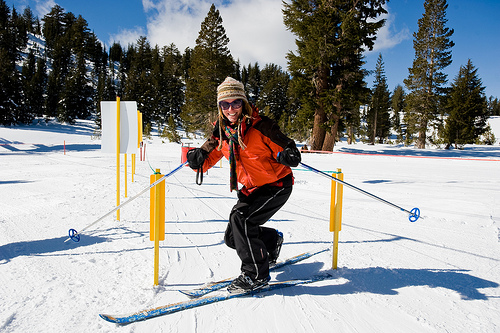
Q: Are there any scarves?
A: Yes, there is a scarf.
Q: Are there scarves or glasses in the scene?
A: Yes, there is a scarf.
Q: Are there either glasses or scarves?
A: Yes, there is a scarf.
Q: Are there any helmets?
A: No, there are no helmets.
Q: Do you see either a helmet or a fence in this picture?
A: No, there are no helmets or fences.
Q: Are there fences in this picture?
A: No, there are no fences.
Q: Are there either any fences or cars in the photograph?
A: No, there are no fences or cars.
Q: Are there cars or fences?
A: No, there are no fences or cars.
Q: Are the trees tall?
A: Yes, the trees are tall.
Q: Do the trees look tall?
A: Yes, the trees are tall.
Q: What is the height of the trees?
A: The trees are tall.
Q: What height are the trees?
A: The trees are tall.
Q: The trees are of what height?
A: The trees are tall.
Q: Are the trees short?
A: No, the trees are tall.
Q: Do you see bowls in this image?
A: No, there are no bowls.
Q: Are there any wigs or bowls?
A: No, there are no bowls or wigs.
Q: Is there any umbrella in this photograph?
A: No, there are no umbrellas.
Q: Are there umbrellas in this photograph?
A: No, there are no umbrellas.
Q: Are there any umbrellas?
A: No, there are no umbrellas.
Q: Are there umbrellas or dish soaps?
A: No, there are no umbrellas or dish soaps.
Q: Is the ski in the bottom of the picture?
A: Yes, the ski is in the bottom of the image.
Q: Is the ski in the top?
A: No, the ski is in the bottom of the image.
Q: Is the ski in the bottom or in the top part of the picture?
A: The ski is in the bottom of the image.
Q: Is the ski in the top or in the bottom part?
A: The ski is in the bottom of the image.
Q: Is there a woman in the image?
A: Yes, there is a woman.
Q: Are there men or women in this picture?
A: Yes, there is a woman.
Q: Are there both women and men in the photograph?
A: No, there is a woman but no men.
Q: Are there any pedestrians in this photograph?
A: No, there are no pedestrians.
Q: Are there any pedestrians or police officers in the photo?
A: No, there are no pedestrians or police officers.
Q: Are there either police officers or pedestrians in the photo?
A: No, there are no pedestrians or police officers.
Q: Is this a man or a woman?
A: This is a woman.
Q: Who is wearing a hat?
A: The woman is wearing a hat.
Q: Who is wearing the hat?
A: The woman is wearing a hat.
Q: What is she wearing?
A: The woman is wearing a hat.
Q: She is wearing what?
A: The woman is wearing a hat.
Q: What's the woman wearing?
A: The woman is wearing a hat.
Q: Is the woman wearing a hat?
A: Yes, the woman is wearing a hat.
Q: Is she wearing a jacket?
A: No, the woman is wearing a hat.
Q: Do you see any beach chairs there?
A: No, there are no beach chairs.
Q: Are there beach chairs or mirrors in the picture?
A: No, there are no beach chairs or mirrors.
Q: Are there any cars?
A: No, there are no cars.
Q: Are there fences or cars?
A: No, there are no cars or fences.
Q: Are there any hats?
A: Yes, there is a hat.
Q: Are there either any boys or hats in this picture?
A: Yes, there is a hat.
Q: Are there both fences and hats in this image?
A: No, there is a hat but no fences.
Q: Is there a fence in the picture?
A: No, there are no fences.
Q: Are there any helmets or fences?
A: No, there are no fences or helmets.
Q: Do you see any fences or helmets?
A: No, there are no fences or helmets.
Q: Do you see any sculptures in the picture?
A: No, there are no sculptures.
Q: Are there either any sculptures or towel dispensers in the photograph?
A: No, there are no sculptures or towel dispensers.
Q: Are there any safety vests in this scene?
A: No, there are no safety vests.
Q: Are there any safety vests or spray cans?
A: No, there are no safety vests or spray cans.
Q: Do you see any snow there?
A: Yes, there is snow.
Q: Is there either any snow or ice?
A: Yes, there is snow.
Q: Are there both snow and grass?
A: No, there is snow but no grass.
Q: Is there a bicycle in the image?
A: No, there are no bicycles.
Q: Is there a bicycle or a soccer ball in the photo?
A: No, there are no bicycles or soccer balls.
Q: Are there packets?
A: No, there are no packets.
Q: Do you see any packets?
A: No, there are no packets.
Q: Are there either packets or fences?
A: No, there are no packets or fences.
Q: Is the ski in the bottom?
A: Yes, the ski is in the bottom of the image.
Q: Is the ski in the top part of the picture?
A: No, the ski is in the bottom of the image.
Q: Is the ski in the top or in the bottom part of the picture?
A: The ski is in the bottom of the image.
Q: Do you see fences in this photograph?
A: No, there are no fences.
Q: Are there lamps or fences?
A: No, there are no fences or lamps.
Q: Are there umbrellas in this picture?
A: No, there are no umbrellas.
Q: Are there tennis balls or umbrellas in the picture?
A: No, there are no umbrellas or tennis balls.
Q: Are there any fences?
A: No, there are no fences.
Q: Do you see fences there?
A: No, there are no fences.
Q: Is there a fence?
A: No, there are no fences.